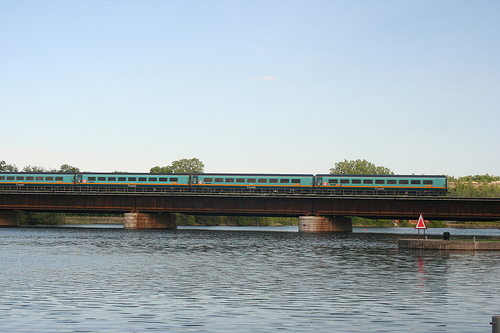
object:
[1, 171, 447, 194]
train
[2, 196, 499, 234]
bridge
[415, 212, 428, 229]
sign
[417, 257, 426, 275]
reflection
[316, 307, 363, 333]
water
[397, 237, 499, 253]
platform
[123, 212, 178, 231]
pillar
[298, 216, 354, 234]
pillar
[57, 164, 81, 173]
trees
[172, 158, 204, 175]
trees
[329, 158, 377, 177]
trees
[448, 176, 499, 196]
hill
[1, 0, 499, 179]
sky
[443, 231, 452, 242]
object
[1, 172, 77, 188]
train car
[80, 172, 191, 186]
train car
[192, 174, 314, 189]
train car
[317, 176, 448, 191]
train car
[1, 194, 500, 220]
train track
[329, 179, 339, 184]
window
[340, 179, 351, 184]
window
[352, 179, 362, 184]
window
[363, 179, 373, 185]
window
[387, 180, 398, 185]
window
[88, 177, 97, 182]
window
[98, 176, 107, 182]
window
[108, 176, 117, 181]
window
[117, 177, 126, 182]
window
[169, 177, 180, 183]
window